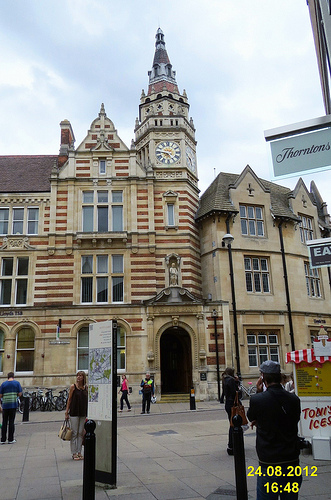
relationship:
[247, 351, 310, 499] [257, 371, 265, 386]
man on h phone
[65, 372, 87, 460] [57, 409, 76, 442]
woman has a purse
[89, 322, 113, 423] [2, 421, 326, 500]
map on sidewalk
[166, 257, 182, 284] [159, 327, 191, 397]
statue over door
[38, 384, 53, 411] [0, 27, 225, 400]
bike by building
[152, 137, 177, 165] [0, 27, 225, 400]
clock on building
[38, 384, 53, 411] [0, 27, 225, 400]
bike outside building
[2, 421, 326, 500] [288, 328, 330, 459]
sidewalk by stand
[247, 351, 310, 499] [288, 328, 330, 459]
man by stand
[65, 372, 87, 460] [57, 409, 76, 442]
woman holding purse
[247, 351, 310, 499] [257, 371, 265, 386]
man talking on h phone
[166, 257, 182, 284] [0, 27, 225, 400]
statue on building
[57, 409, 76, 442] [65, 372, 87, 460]
purse held by woman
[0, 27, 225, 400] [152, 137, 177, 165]
building has a clock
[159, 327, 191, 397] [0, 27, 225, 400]
door on building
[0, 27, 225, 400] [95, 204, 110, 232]
building has a window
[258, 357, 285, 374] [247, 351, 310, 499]
hat on man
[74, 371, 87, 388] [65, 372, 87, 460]
head of woman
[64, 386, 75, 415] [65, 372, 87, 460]
arm of woman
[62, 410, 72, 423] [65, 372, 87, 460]
hand of woman